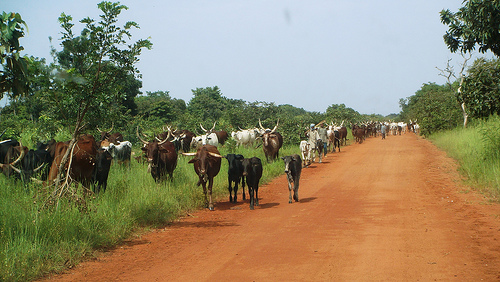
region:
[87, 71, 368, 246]
Cattle on the road.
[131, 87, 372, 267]
Steer with large horns.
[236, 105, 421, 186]
Road between the grass.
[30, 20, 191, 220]
Trees on the grass.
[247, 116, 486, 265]
Dirt road with cattle.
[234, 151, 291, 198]
Smaller cattle on the road.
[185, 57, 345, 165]
Trees in the background.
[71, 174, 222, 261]
Tall grass by the road.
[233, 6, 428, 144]
Blue sky in the background.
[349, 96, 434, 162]
Cattle in the distance.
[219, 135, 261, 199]
black cows on road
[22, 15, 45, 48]
white clouds against blue sky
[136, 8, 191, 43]
white clouds against blue sky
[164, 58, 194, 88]
white clouds against blue sky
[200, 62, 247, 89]
white clouds against blue sky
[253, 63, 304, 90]
white clouds against blue sky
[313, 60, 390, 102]
white clouds against blue sky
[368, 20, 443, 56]
white clouds against blue sky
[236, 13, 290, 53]
white clouds against blue sky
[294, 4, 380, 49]
white clouds against blue sky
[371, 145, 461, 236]
red clay dirt road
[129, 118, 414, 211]
large cattle drive on dirt road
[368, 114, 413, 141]
farmhand moving cattle down the road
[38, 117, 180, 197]
large cows in the grass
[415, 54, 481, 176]
large tree next to dirt road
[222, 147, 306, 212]
calves walking down dirt road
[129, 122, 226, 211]
large horned steer in the grass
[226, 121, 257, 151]
large white cow with horns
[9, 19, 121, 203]
cows standing underneath a tree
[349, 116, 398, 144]
man walking with herd of cattle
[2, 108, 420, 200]
bunch of cattle in a path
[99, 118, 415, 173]
white cattle walking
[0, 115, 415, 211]
bunch of cattle walking together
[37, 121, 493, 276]
sandy road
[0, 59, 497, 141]
bunch of bushes behind cattle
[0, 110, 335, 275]
green grass in the left side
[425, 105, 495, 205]
green grass in the right side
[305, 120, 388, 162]
three men walking with a cattle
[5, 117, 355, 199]
bulls with big white chunks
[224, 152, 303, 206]
three calves in the middle of path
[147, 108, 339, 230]
Group of animals on a road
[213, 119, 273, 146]
white cow in a field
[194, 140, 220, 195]
brown cow in a field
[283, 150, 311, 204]
goat in the road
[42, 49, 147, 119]
trees in a field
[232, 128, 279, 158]
white cow in the field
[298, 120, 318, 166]
white cow in the field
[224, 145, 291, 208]
black cow on the road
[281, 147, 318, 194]
goat on the dirt road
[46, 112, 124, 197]
brown cow in the field